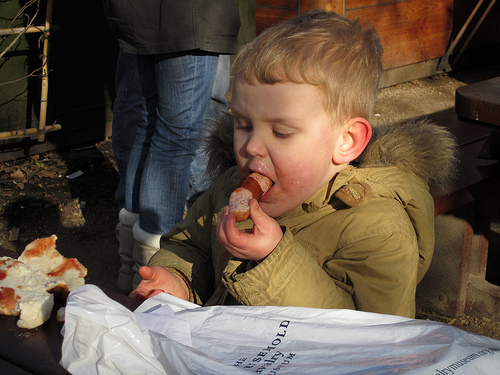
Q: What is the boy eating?
A: Hot dog.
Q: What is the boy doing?
A: Eating.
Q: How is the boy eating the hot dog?
A: With hands.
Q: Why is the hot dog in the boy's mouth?
A: Eating it.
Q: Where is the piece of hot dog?
A: In the boy's mouth.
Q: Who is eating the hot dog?
A: A boy.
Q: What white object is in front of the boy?
A: Plastic bag.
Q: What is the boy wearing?
A: Brown coat.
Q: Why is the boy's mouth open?
A: Eating a hot dog.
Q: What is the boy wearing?
A: Brown jacket.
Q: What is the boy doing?
A: Eating.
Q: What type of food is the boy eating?
A: Hot dog.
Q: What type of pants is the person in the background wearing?
A: Jeans.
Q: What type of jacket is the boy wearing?
A: Winter jacket.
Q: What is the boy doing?
A: Eating.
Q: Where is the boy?
A: In the chair.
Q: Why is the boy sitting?
A: Because he is eating.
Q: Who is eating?
A: The boy.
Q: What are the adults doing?
A: Standing.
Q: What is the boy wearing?
A: A coat.